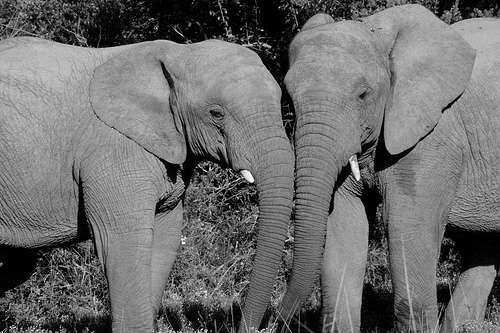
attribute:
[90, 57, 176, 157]
ear — floppy, gray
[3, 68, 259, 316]
elephant — here, wrinkled, gray, happy, looking, little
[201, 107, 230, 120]
eye — black, small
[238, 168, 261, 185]
tusk — white, short, little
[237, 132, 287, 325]
trunk — long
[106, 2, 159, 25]
trees — background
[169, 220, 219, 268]
bushes — background, leaves